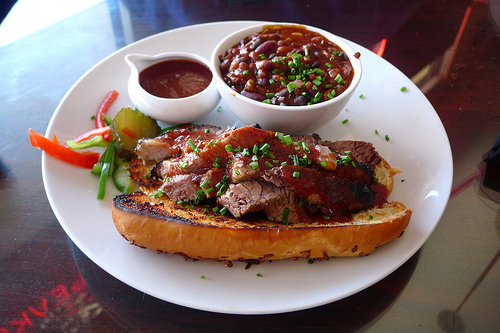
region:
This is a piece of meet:
[273, 163, 369, 210]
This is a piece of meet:
[221, 183, 294, 217]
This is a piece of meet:
[163, 167, 228, 198]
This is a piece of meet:
[199, 118, 357, 170]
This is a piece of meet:
[133, 135, 223, 162]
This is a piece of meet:
[290, 126, 410, 186]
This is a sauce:
[118, 47, 224, 127]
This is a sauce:
[212, 26, 368, 123]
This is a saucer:
[123, 47, 233, 132]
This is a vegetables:
[43, 97, 145, 187]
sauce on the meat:
[126, 116, 368, 222]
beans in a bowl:
[221, 26, 353, 116]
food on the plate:
[45, 25, 346, 329]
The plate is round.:
[40, 15, 455, 317]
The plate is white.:
[32, 7, 442, 318]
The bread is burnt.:
[111, 189, 183, 221]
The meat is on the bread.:
[132, 122, 399, 222]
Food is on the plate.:
[47, 14, 457, 317]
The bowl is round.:
[207, 18, 364, 135]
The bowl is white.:
[212, 20, 372, 140]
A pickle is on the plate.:
[108, 106, 162, 161]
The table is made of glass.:
[18, 17, 114, 52]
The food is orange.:
[26, 126, 64, 163]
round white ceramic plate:
[40, 18, 456, 313]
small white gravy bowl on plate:
[120, 50, 216, 125]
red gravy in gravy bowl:
[137, 56, 207, 96]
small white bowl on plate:
[210, 20, 360, 131]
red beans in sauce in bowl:
[216, 21, 351, 101]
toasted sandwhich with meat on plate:
[111, 121, 408, 256]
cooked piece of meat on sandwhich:
[212, 175, 307, 220]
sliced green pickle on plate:
[106, 105, 161, 155]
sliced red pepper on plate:
[26, 125, 96, 165]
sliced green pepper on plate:
[95, 141, 111, 198]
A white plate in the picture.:
[420, 123, 447, 180]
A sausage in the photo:
[122, 207, 186, 251]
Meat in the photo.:
[320, 178, 367, 206]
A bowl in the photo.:
[247, 99, 292, 123]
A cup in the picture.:
[177, 94, 202, 111]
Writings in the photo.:
[17, 289, 76, 329]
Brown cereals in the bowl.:
[233, 52, 252, 87]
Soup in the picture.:
[163, 73, 186, 88]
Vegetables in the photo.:
[98, 158, 125, 180]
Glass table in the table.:
[26, 45, 65, 74]